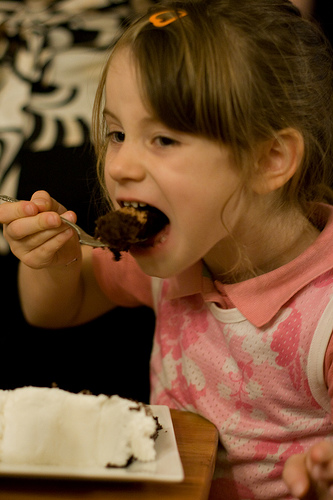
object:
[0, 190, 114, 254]
fork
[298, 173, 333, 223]
hair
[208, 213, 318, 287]
neck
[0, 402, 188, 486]
plate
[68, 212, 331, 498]
shirt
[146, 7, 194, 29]
barrette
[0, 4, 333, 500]
house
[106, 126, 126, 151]
eyes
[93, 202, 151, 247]
cake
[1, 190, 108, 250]
spoon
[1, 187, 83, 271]
hand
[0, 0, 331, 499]
child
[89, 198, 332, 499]
pink blouse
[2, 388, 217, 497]
table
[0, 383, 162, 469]
cake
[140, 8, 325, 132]
hair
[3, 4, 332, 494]
girl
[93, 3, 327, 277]
head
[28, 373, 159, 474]
pastry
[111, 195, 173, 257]
mouth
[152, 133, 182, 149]
eyes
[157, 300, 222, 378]
print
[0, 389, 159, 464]
frosting